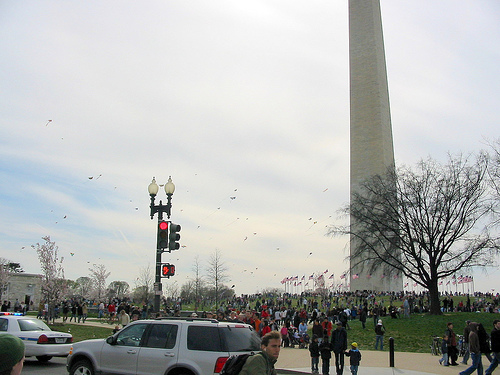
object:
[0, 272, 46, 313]
building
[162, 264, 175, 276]
crosswalk sign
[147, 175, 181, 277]
streetlight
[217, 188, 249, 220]
birds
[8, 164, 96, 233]
sky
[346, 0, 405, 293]
cement monument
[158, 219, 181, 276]
sign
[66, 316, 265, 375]
suv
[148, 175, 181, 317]
lamppost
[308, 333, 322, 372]
children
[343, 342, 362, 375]
boy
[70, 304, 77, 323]
people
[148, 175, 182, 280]
lights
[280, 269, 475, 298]
flags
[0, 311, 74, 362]
police car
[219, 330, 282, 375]
man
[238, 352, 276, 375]
parka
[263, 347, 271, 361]
earbuds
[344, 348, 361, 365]
coat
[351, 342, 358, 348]
hat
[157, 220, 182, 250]
traffic lights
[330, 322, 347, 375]
adult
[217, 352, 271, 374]
backpack